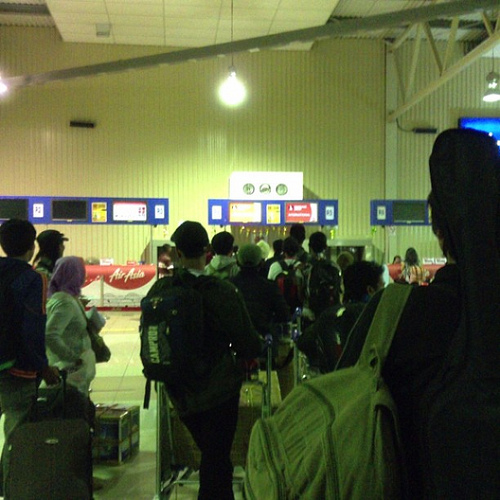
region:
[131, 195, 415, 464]
People are in line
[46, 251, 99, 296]
The woman has a purple cloth over her head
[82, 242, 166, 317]
The sign is red and white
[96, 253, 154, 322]
The sign reads Air Asia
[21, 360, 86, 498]
The man is holding a wheeled suitcase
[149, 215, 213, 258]
The man is wearing a black hat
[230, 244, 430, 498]
The person is holding a light colored backpack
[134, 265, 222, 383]
The man has a backpack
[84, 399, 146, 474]
Boxes are on the floor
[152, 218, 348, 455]
People are in line at the airport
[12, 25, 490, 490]
people with luggage waiting on long lines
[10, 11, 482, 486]
large room with elevated ceiling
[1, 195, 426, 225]
rectangular blue panels containing smaller panels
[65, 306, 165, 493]
floor covered in yellow and tan tiles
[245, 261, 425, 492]
wide and droopy backpack over shoulder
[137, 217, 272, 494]
person in dark clothes in back of luggage cart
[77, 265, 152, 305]
red and white counter with name of airline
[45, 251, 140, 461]
woman with hand on hip next to tied box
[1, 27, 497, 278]
yellow and grey vertical lines across wall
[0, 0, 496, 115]
round light under supporting beams and ceiling panel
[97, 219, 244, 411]
man is carrying a backpack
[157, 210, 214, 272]
the cap is black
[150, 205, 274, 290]
the cap is black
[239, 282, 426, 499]
Light colored backpack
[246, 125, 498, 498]
Person with a backpack on their shoulder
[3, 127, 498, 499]
Large group of people waiting a line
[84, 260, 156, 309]
Red and white Air Asia counter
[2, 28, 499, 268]
Tall yellow wall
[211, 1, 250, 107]
Bright light hanging on a single wire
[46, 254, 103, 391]
Woman with a purple scarf on her head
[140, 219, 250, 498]
Man standing with his legs crossed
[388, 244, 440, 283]
Two people separated by a red counter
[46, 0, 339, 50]
White ceiling tiles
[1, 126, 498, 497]
Crowd of people at airport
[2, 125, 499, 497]
People waiting in line for tickets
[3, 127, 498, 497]
Travelers waiting to board airplane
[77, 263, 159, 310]
Red and white front of ticket counter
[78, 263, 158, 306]
Counter for Air Asia airline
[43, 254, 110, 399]
Woman wearing purple headscarf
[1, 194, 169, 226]
Electronic sign hanging on wall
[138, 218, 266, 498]
Person wearing backpack with white writing on it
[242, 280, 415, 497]
Tan backpack hanging on a person's shoulder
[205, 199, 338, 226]
Multicolored informational sign with bright blue background